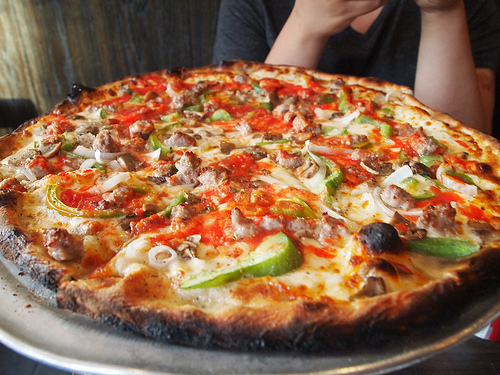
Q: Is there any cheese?
A: Yes, there is cheese.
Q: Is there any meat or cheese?
A: Yes, there is cheese.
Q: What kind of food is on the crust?
A: The food is cheese.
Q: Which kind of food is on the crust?
A: The food is cheese.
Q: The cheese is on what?
A: The cheese is on the crust.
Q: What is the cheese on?
A: The cheese is on the crust.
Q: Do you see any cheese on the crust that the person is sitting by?
A: Yes, there is cheese on the crust.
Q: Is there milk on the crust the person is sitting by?
A: No, there is cheese on the crust.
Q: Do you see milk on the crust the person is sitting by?
A: No, there is cheese on the crust.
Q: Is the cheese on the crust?
A: Yes, the cheese is on the crust.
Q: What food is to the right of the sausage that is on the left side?
A: The food is cheese.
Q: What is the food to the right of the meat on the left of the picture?
A: The food is cheese.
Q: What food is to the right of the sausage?
A: The food is cheese.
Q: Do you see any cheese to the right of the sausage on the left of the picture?
A: Yes, there is cheese to the right of the sausage.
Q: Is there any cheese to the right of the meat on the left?
A: Yes, there is cheese to the right of the sausage.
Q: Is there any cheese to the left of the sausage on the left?
A: No, the cheese is to the right of the sausage.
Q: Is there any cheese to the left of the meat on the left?
A: No, the cheese is to the right of the sausage.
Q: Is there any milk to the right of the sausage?
A: No, there is cheese to the right of the sausage.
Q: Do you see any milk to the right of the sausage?
A: No, there is cheese to the right of the sausage.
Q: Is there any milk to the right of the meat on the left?
A: No, there is cheese to the right of the sausage.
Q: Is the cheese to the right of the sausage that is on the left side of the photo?
A: Yes, the cheese is to the right of the sausage.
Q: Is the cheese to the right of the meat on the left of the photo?
A: Yes, the cheese is to the right of the sausage.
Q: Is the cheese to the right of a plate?
A: No, the cheese is to the right of the sausage.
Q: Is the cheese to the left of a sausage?
A: No, the cheese is to the right of a sausage.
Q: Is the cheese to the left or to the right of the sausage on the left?
A: The cheese is to the right of the sausage.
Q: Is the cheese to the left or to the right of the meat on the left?
A: The cheese is to the right of the sausage.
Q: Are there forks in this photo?
A: No, there are no forks.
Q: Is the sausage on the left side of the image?
A: Yes, the sausage is on the left of the image.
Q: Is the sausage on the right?
A: No, the sausage is on the left of the image.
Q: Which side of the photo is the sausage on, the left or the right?
A: The sausage is on the left of the image.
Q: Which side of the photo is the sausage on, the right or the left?
A: The sausage is on the left of the image.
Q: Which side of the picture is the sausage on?
A: The sausage is on the left of the image.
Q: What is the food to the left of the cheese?
A: The food is a sausage.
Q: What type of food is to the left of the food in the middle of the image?
A: The food is a sausage.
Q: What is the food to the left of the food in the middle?
A: The food is a sausage.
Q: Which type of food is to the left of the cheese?
A: The food is a sausage.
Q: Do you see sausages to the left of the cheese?
A: Yes, there is a sausage to the left of the cheese.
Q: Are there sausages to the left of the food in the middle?
A: Yes, there is a sausage to the left of the cheese.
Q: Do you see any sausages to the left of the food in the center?
A: Yes, there is a sausage to the left of the cheese.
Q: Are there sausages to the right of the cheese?
A: No, the sausage is to the left of the cheese.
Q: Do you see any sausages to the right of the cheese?
A: No, the sausage is to the left of the cheese.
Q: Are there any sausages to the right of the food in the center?
A: No, the sausage is to the left of the cheese.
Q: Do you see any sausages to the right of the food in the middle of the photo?
A: No, the sausage is to the left of the cheese.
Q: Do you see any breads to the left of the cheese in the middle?
A: No, there is a sausage to the left of the cheese.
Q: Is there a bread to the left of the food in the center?
A: No, there is a sausage to the left of the cheese.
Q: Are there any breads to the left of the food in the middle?
A: No, there is a sausage to the left of the cheese.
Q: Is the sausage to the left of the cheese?
A: Yes, the sausage is to the left of the cheese.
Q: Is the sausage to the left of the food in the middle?
A: Yes, the sausage is to the left of the cheese.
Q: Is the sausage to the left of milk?
A: No, the sausage is to the left of the cheese.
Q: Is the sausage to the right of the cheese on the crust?
A: No, the sausage is to the left of the cheese.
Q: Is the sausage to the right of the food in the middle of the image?
A: No, the sausage is to the left of the cheese.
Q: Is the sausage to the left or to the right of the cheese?
A: The sausage is to the left of the cheese.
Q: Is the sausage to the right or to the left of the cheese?
A: The sausage is to the left of the cheese.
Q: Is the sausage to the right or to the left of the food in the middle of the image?
A: The sausage is to the left of the cheese.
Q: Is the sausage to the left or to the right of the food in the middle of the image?
A: The sausage is to the left of the cheese.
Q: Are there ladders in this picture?
A: No, there are no ladders.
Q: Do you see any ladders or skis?
A: No, there are no ladders or skis.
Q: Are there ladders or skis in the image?
A: No, there are no ladders or skis.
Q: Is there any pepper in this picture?
A: Yes, there is a pepper.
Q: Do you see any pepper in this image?
A: Yes, there is a pepper.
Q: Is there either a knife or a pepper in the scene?
A: Yes, there is a pepper.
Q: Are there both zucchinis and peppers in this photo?
A: No, there is a pepper but no zucchinis.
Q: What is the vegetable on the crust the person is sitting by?
A: The vegetable is a pepper.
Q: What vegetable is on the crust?
A: The vegetable is a pepper.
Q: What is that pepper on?
A: The pepper is on the crust.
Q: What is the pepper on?
A: The pepper is on the crust.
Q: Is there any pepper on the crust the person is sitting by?
A: Yes, there is a pepper on the crust.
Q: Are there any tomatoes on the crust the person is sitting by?
A: No, there is a pepper on the crust.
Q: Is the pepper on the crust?
A: Yes, the pepper is on the crust.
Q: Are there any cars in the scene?
A: No, there are no cars.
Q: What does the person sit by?
A: The person sits by the crust.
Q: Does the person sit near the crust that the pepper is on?
A: Yes, the person sits near the crust.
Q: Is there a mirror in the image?
A: No, there are no mirrors.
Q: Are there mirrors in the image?
A: No, there are no mirrors.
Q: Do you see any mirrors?
A: No, there are no mirrors.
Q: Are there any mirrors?
A: No, there are no mirrors.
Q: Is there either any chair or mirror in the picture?
A: No, there are no mirrors or chairs.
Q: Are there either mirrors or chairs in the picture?
A: No, there are no mirrors or chairs.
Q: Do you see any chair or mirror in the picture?
A: No, there are no mirrors or chairs.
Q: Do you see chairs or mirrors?
A: No, there are no mirrors or chairs.